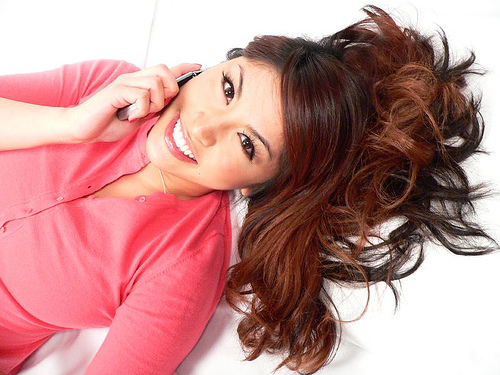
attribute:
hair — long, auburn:
[274, 57, 423, 322]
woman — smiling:
[15, 51, 406, 365]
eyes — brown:
[205, 63, 300, 199]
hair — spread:
[265, 43, 469, 371]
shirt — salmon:
[32, 66, 241, 363]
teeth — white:
[164, 124, 189, 160]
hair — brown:
[256, 242, 326, 291]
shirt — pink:
[20, 212, 117, 269]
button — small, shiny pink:
[19, 203, 39, 219]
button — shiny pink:
[1, 215, 11, 233]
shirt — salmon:
[42, 63, 126, 234]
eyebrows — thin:
[202, 35, 311, 224]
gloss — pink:
[156, 112, 202, 176]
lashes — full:
[212, 30, 321, 190]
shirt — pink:
[63, 172, 158, 272]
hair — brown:
[281, 153, 420, 177]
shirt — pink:
[63, 185, 118, 259]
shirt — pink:
[49, 167, 99, 229]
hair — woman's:
[279, 21, 472, 210]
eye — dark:
[223, 129, 264, 167]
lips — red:
[163, 106, 197, 166]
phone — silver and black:
[116, 68, 201, 123]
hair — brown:
[234, 6, 498, 374]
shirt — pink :
[0, 57, 236, 372]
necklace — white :
[154, 165, 170, 203]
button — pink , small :
[141, 196, 146, 203]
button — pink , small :
[56, 193, 66, 203]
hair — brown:
[328, 69, 458, 243]